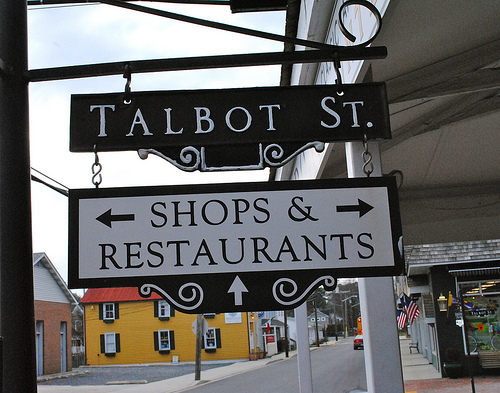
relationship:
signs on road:
[82, 102, 395, 277] [186, 338, 364, 392]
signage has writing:
[70, 84, 389, 171] [94, 110, 364, 133]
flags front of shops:
[396, 296, 428, 334] [422, 288, 499, 377]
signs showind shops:
[68, 183, 408, 315] [422, 288, 499, 377]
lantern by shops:
[434, 292, 451, 317] [422, 288, 499, 377]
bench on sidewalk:
[406, 325, 419, 356] [391, 326, 434, 386]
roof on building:
[79, 284, 150, 301] [71, 285, 257, 377]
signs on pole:
[82, 102, 395, 277] [316, 79, 412, 385]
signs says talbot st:
[68, 183, 408, 315] [94, 95, 369, 138]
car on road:
[346, 319, 373, 353] [282, 346, 357, 391]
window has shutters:
[88, 334, 124, 363] [99, 331, 109, 356]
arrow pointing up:
[77, 202, 148, 230] [223, 273, 248, 362]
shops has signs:
[422, 288, 499, 377] [82, 102, 395, 277]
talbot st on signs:
[94, 95, 369, 138] [82, 102, 395, 277]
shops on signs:
[422, 288, 499, 377] [82, 102, 395, 277]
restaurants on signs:
[77, 232, 384, 270] [82, 102, 395, 277]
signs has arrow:
[82, 102, 395, 277] [77, 202, 148, 230]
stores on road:
[422, 288, 499, 377] [186, 338, 364, 392]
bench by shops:
[409, 339, 420, 355] [435, 267, 500, 377]